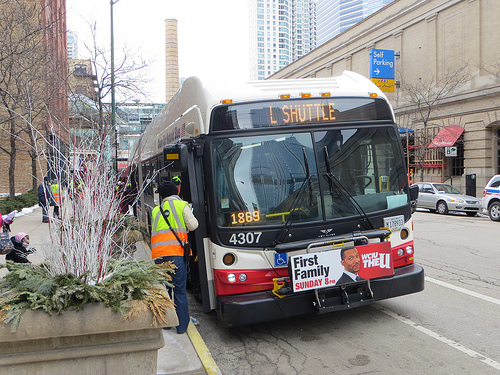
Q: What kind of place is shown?
A: It is a street.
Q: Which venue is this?
A: This is a street.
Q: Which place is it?
A: It is a street.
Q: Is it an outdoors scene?
A: Yes, it is outdoors.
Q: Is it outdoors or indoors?
A: It is outdoors.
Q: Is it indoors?
A: No, it is outdoors.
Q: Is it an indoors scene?
A: No, it is outdoors.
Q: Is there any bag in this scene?
A: Yes, there is a bag.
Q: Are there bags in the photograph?
A: Yes, there is a bag.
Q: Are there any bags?
A: Yes, there is a bag.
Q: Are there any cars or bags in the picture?
A: Yes, there is a bag.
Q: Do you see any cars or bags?
A: Yes, there is a bag.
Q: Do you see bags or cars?
A: Yes, there is a bag.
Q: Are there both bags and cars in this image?
A: Yes, there are both a bag and a car.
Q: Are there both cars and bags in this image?
A: Yes, there are both a bag and a car.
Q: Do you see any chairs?
A: No, there are no chairs.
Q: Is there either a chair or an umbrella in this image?
A: No, there are no chairs or umbrellas.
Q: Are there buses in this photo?
A: Yes, there is a bus.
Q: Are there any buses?
A: Yes, there is a bus.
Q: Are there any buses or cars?
A: Yes, there is a bus.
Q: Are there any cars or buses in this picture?
A: Yes, there is a bus.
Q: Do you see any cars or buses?
A: Yes, there is a bus.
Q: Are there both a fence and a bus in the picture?
A: No, there is a bus but no fences.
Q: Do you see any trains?
A: No, there are no trains.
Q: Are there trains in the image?
A: No, there are no trains.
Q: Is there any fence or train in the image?
A: No, there are no trains or fences.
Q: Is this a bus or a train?
A: This is a bus.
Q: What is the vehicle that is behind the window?
A: The vehicle is a bus.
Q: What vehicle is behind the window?
A: The vehicle is a bus.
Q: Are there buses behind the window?
A: Yes, there is a bus behind the window.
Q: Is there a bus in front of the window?
A: No, the bus is behind the window.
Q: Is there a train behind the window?
A: No, there is a bus behind the window.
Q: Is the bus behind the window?
A: Yes, the bus is behind the window.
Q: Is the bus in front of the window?
A: No, the bus is behind the window.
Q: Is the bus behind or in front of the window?
A: The bus is behind the window.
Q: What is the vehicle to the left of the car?
A: The vehicle is a bus.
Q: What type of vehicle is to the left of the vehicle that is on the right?
A: The vehicle is a bus.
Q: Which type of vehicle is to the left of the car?
A: The vehicle is a bus.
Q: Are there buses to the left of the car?
A: Yes, there is a bus to the left of the car.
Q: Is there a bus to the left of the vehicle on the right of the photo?
A: Yes, there is a bus to the left of the car.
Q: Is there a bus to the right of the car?
A: No, the bus is to the left of the car.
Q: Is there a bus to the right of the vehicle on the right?
A: No, the bus is to the left of the car.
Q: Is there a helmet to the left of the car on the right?
A: No, there is a bus to the left of the car.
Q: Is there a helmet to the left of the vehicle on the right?
A: No, there is a bus to the left of the car.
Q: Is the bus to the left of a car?
A: Yes, the bus is to the left of a car.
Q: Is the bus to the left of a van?
A: No, the bus is to the left of a car.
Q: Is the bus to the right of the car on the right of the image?
A: No, the bus is to the left of the car.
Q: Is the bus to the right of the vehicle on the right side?
A: No, the bus is to the left of the car.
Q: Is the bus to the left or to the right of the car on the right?
A: The bus is to the left of the car.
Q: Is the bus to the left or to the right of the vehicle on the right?
A: The bus is to the left of the car.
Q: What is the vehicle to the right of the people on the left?
A: The vehicle is a bus.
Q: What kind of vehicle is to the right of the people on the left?
A: The vehicle is a bus.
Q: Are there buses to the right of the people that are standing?
A: Yes, there is a bus to the right of the people.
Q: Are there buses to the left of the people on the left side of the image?
A: No, the bus is to the right of the people.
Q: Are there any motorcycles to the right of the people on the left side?
A: No, there is a bus to the right of the people.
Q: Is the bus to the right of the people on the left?
A: Yes, the bus is to the right of the people.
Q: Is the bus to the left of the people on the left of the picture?
A: No, the bus is to the right of the people.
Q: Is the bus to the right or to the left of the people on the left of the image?
A: The bus is to the right of the people.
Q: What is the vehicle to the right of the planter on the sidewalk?
A: The vehicle is a bus.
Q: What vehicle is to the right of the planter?
A: The vehicle is a bus.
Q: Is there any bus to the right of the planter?
A: Yes, there is a bus to the right of the planter.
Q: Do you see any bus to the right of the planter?
A: Yes, there is a bus to the right of the planter.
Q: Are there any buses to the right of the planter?
A: Yes, there is a bus to the right of the planter.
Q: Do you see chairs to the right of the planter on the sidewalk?
A: No, there is a bus to the right of the planter.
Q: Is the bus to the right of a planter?
A: Yes, the bus is to the right of a planter.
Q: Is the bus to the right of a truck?
A: No, the bus is to the right of a planter.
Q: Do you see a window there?
A: Yes, there is a window.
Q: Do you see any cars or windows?
A: Yes, there is a window.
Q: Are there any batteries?
A: No, there are no batteries.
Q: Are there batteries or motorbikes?
A: No, there are no batteries or motorbikes.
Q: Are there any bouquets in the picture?
A: No, there are no bouquets.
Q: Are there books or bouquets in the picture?
A: No, there are no bouquets or books.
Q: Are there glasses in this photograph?
A: No, there are no glasses.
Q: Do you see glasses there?
A: No, there are no glasses.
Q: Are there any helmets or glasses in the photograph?
A: No, there are no glasses or helmets.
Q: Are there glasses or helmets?
A: No, there are no glasses or helmets.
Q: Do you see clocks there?
A: No, there are no clocks.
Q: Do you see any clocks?
A: No, there are no clocks.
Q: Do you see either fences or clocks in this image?
A: No, there are no clocks or fences.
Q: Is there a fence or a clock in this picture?
A: No, there are no clocks or fences.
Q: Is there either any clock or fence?
A: No, there are no clocks or fences.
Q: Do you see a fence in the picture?
A: No, there are no fences.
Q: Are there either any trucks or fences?
A: No, there are no fences or trucks.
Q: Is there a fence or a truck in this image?
A: No, there are no fences or trucks.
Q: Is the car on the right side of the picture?
A: Yes, the car is on the right of the image.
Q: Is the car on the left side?
A: No, the car is on the right of the image.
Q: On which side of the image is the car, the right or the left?
A: The car is on the right of the image.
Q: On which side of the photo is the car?
A: The car is on the right of the image.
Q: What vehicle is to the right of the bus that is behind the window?
A: The vehicle is a car.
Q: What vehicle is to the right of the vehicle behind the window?
A: The vehicle is a car.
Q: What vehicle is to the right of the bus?
A: The vehicle is a car.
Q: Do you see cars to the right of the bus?
A: Yes, there is a car to the right of the bus.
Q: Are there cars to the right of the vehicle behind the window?
A: Yes, there is a car to the right of the bus.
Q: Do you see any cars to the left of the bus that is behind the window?
A: No, the car is to the right of the bus.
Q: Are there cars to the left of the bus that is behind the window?
A: No, the car is to the right of the bus.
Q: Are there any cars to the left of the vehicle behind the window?
A: No, the car is to the right of the bus.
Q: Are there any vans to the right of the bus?
A: No, there is a car to the right of the bus.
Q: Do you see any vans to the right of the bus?
A: No, there is a car to the right of the bus.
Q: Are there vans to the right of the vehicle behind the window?
A: No, there is a car to the right of the bus.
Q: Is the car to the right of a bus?
A: Yes, the car is to the right of a bus.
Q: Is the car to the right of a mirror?
A: No, the car is to the right of a bus.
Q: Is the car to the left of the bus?
A: No, the car is to the right of the bus.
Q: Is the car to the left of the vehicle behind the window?
A: No, the car is to the right of the bus.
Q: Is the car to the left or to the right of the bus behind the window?
A: The car is to the right of the bus.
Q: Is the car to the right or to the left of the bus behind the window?
A: The car is to the right of the bus.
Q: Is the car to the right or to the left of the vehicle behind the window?
A: The car is to the right of the bus.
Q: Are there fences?
A: No, there are no fences.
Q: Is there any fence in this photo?
A: No, there are no fences.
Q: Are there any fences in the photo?
A: No, there are no fences.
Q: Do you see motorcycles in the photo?
A: No, there are no motorcycles.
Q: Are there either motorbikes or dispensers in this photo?
A: No, there are no motorbikes or dispensers.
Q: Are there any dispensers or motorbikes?
A: No, there are no motorbikes or dispensers.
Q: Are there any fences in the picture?
A: No, there are no fences.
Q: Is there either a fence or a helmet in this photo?
A: No, there are no fences or helmets.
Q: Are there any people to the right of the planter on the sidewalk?
A: Yes, there is a person to the right of the planter.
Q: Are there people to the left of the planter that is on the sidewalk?
A: No, the person is to the right of the planter.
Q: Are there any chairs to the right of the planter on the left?
A: No, there is a person to the right of the planter.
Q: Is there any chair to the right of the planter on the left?
A: No, there is a person to the right of the planter.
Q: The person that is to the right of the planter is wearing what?
A: The person is wearing a vest.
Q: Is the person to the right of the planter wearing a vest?
A: Yes, the person is wearing a vest.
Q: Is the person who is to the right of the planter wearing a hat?
A: No, the person is wearing a vest.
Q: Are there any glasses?
A: No, there are no glasses.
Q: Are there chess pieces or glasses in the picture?
A: No, there are no glasses or chess pieces.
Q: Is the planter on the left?
A: Yes, the planter is on the left of the image.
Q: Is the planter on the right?
A: No, the planter is on the left of the image.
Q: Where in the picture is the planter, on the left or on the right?
A: The planter is on the left of the image.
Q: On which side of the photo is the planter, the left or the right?
A: The planter is on the left of the image.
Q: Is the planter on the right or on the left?
A: The planter is on the left of the image.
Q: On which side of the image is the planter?
A: The planter is on the left of the image.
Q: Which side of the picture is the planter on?
A: The planter is on the left of the image.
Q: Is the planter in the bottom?
A: Yes, the planter is in the bottom of the image.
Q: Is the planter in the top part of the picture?
A: No, the planter is in the bottom of the image.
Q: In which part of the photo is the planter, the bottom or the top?
A: The planter is in the bottom of the image.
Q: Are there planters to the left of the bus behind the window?
A: Yes, there is a planter to the left of the bus.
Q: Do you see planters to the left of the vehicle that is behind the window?
A: Yes, there is a planter to the left of the bus.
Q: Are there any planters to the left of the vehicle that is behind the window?
A: Yes, there is a planter to the left of the bus.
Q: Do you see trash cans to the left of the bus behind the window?
A: No, there is a planter to the left of the bus.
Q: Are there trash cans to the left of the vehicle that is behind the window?
A: No, there is a planter to the left of the bus.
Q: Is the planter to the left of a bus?
A: Yes, the planter is to the left of a bus.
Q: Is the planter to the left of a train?
A: No, the planter is to the left of a bus.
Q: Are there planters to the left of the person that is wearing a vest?
A: Yes, there is a planter to the left of the person.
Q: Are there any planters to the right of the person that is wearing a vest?
A: No, the planter is to the left of the person.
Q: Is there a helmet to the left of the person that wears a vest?
A: No, there is a planter to the left of the person.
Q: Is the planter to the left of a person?
A: Yes, the planter is to the left of a person.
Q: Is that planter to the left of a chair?
A: No, the planter is to the left of a person.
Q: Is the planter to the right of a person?
A: No, the planter is to the left of a person.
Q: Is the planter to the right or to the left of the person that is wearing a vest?
A: The planter is to the left of the person.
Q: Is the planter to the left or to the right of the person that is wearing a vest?
A: The planter is to the left of the person.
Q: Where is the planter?
A: The planter is on the sidewalk.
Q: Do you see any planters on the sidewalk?
A: Yes, there is a planter on the sidewalk.